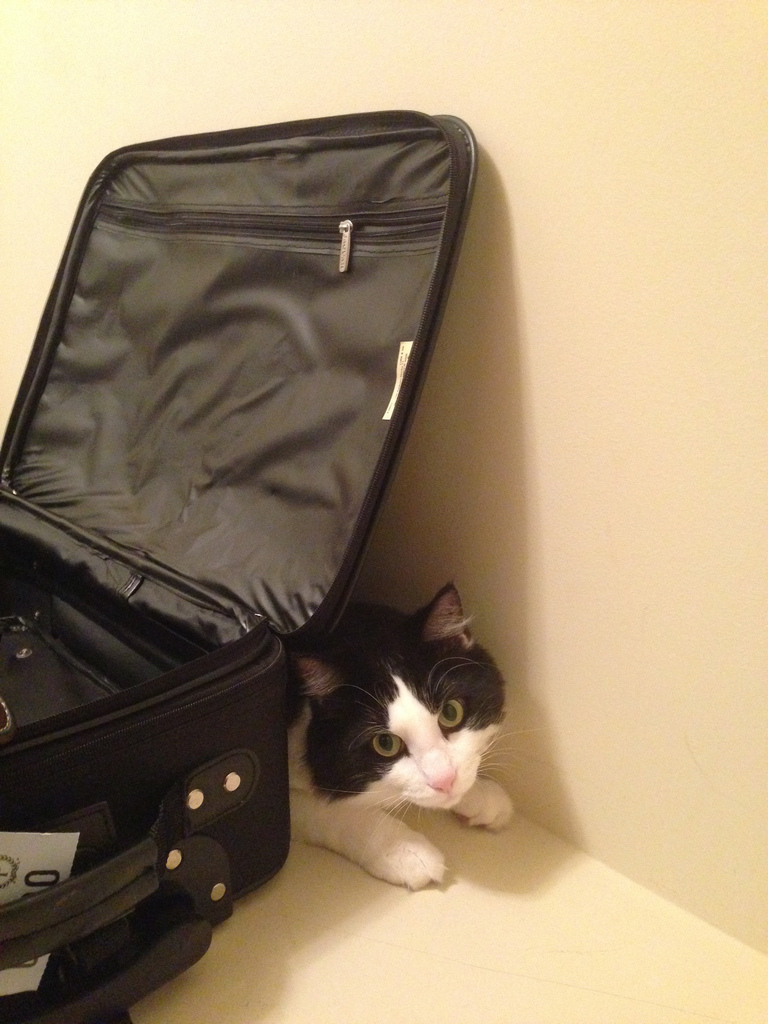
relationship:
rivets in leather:
[170, 730, 260, 858] [80, 164, 363, 663]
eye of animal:
[429, 689, 484, 751] [327, 628, 568, 998]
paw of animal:
[363, 818, 545, 940] [264, 558, 653, 1021]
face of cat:
[338, 589, 527, 840] [277, 559, 568, 938]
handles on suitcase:
[50, 768, 267, 995] [55, 89, 402, 873]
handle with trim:
[84, 773, 290, 1015] [137, 759, 318, 923]